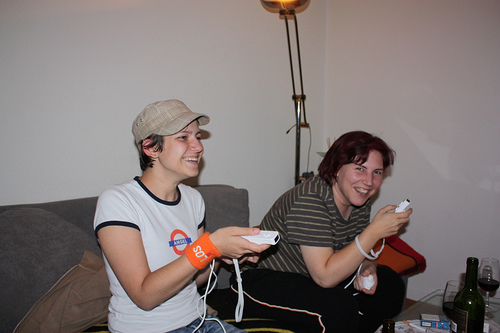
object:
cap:
[130, 99, 212, 145]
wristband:
[184, 231, 220, 272]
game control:
[234, 228, 283, 245]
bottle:
[452, 256, 487, 333]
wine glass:
[477, 256, 499, 322]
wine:
[479, 276, 499, 290]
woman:
[92, 98, 270, 332]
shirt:
[91, 177, 213, 333]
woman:
[232, 130, 414, 332]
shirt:
[249, 174, 372, 276]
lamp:
[260, 0, 313, 187]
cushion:
[3, 208, 106, 333]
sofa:
[0, 183, 249, 333]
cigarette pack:
[418, 311, 453, 330]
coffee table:
[375, 286, 500, 333]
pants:
[227, 265, 409, 333]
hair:
[317, 131, 397, 184]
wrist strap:
[231, 255, 247, 323]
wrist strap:
[352, 233, 387, 259]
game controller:
[393, 197, 410, 213]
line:
[229, 285, 326, 332]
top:
[465, 256, 481, 271]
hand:
[369, 203, 414, 237]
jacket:
[14, 250, 111, 332]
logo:
[168, 228, 194, 256]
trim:
[135, 176, 182, 206]